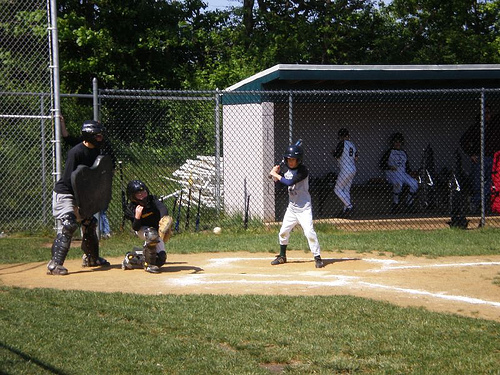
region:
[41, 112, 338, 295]
Three baseball players on a field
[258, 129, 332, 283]
Boy holding a bat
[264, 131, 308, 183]
Bat is on right shoulder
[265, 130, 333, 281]
Boy wears a blue helmet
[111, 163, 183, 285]
Catcher is bend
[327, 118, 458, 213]
Baseball players in rest area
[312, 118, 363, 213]
Player wears team uniform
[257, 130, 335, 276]
Boy wears white pants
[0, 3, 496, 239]
Field has a fence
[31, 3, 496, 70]
Trees behind playing field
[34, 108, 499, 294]
boys are playing baseball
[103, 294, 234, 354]
grass is green in color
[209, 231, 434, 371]
white lines are drawn in ground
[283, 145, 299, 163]
helmet is black in color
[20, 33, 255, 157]
trees are behind the fence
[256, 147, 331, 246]
players dress is white and black in color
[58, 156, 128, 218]
shield is black in color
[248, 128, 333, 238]
boy swings the baseball bat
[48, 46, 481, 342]
daytime picture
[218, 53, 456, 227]
shed is white color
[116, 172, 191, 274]
catcher waiting for the ball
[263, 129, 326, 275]
boy playing baseball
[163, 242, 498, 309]
white lines in the dirt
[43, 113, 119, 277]
umpire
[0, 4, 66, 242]
page fence behind the players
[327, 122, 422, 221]
players in the dugout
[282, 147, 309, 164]
players blue helmet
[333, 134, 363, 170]
white shirt with a number on the bag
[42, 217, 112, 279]
shin pads for protection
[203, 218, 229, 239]
baseball sailing through the air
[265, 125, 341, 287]
the boy is holding a bat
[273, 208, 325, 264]
the pants is white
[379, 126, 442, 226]
the boy is sitting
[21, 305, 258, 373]
the grass is green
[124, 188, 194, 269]
the boy is wearing glove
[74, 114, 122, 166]
the boy is wearing a helmet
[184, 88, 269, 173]
the fence is silver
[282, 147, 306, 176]
the helmet is black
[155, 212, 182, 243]
the gloves is tan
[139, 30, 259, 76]
the trees are green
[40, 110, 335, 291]
Baseball players on a field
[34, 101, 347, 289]
People playing baseball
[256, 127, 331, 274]
Batter miss the ball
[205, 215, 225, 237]
White ball in air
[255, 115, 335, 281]
Boy hold a black bate over his shoulder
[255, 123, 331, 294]
Boy wearing a team shirt white and blue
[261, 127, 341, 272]
Boy has a black helmet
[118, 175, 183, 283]
Catcher is crouched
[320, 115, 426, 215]
Two baseball players inside the rest area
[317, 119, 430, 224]
Players wears team uniform